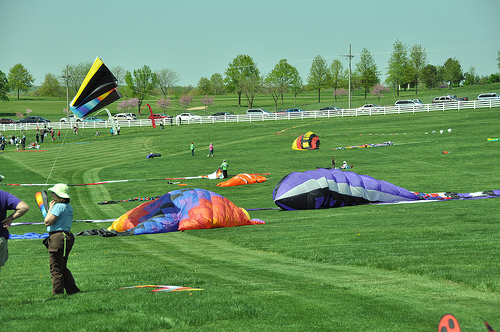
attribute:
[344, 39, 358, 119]
pole — large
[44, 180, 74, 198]
hat — large, shady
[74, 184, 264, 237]
kite — colorful, large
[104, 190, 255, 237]
balloon — rainbow colored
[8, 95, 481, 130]
fence — white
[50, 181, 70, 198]
hat — white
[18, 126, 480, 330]
field — grassy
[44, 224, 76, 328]
pants — dark brown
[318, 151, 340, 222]
balloon —  blue, silver and black 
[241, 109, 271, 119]
car — white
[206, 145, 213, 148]
shirt — pink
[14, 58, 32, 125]
tree — tall green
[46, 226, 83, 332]
pants — brown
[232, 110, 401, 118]
fence. — white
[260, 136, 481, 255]
kite — large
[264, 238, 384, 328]
ground — large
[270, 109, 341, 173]
kite — large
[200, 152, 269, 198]
kite — large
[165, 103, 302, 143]
fence — long, white, picket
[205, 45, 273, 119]
tree — large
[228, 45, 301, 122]
tree — large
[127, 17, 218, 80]
sky — hazy, blue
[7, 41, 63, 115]
tree — large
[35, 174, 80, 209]
hat — tan, sun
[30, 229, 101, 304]
pants — brown, cargo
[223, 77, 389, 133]
fence — long, white